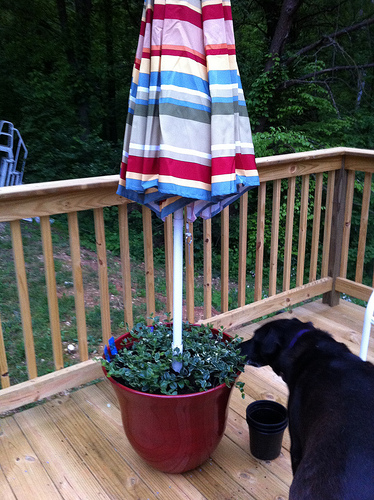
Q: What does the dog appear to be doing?
A: Sniffing plant.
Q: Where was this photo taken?
A: On outside deck.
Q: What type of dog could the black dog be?
A: Labrador retriever.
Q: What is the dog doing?
A: Sniffing the flowers.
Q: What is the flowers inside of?
A: A red pot.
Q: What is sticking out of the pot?
A: An umbrella?.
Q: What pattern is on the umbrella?
A: Stripes.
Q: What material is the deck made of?
A: Wood.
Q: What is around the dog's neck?
A: A blue collar.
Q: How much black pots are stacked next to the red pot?
A: Three.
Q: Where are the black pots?
A: Next to the red pot.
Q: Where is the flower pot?
A: On a deck.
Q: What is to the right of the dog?
A: A chair.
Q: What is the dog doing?
A: Smelling the flowers.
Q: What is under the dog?
A: A black small flower pot.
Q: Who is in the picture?
A: A dog.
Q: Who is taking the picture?
A: The dog owner.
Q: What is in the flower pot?
A: A closed umbrella.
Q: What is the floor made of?
A: Wood.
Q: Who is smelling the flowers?
A: A dog.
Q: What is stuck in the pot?
A: Umbrella.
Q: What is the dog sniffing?
A: Flowers.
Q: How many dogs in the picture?
A: One.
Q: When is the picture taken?
A: During the day.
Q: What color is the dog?
A: Black.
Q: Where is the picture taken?
A: Deck.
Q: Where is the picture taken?
A: Residential deck.